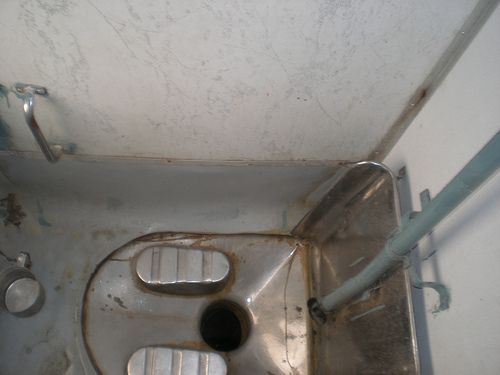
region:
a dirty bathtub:
[69, 123, 449, 370]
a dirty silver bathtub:
[104, 117, 387, 367]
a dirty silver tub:
[83, 121, 499, 346]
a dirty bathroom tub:
[65, 131, 375, 337]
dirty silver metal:
[54, 118, 360, 370]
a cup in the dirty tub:
[4, 227, 133, 369]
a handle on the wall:
[12, 88, 131, 185]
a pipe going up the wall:
[210, 122, 497, 344]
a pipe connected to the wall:
[311, 157, 468, 374]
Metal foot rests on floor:
[110, 235, 246, 372]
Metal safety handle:
[7, 66, 70, 173]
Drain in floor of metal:
[216, 296, 256, 367]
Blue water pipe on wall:
[310, 156, 410, 337]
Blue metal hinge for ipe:
[373, 200, 458, 310]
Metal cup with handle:
[0, 246, 42, 322]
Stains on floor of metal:
[170, 227, 315, 314]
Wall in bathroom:
[155, 59, 292, 149]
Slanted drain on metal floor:
[71, 244, 243, 346]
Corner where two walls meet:
[363, 57, 427, 170]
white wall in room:
[167, 75, 239, 103]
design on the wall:
[173, 51, 315, 133]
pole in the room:
[338, 169, 484, 284]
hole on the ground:
[191, 277, 271, 356]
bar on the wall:
[18, 79, 74, 163]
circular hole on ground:
[183, 293, 260, 358]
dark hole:
[208, 311, 238, 340]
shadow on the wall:
[446, 209, 488, 254]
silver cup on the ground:
[1, 247, 60, 304]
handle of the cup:
[18, 245, 47, 271]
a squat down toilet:
[37, 160, 441, 349]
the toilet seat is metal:
[95, 220, 383, 355]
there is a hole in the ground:
[135, 241, 296, 362]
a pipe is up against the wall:
[187, 210, 472, 298]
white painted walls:
[428, 156, 494, 274]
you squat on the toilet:
[105, 244, 313, 339]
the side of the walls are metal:
[278, 181, 398, 332]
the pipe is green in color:
[285, 214, 487, 283]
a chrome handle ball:
[13, 120, 100, 190]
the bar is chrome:
[12, 126, 146, 178]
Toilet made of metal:
[83, 211, 345, 370]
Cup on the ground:
[0, 245, 54, 320]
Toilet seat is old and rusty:
[87, 219, 292, 371]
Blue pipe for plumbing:
[318, 170, 491, 309]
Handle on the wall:
[9, 87, 86, 173]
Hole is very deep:
[190, 280, 279, 370]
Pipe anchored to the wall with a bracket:
[369, 173, 474, 311]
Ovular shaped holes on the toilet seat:
[130, 216, 217, 373]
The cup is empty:
[6, 255, 46, 318]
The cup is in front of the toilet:
[10, 249, 64, 324]